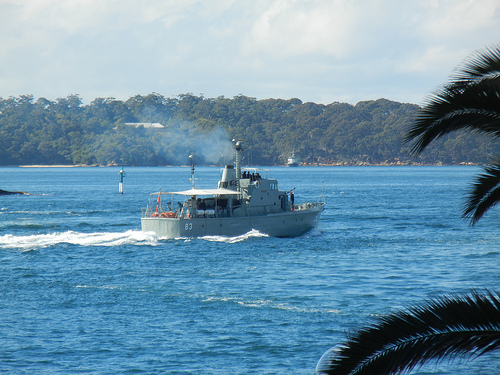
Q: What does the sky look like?
A: Blue with white fluffy clouds.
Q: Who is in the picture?
A: No one.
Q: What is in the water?
A: A boat.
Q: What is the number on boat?
A: 83.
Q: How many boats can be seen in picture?
A: 2.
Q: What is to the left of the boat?
A: Black and white bouys.